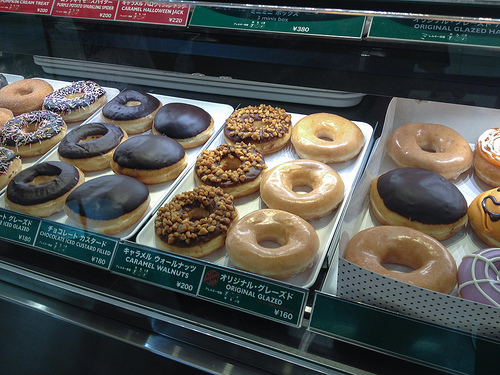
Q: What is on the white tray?
A: Doughnuts.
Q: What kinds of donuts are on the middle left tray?
A: Chocolate frosting donuts.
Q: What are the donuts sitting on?
A: White trays.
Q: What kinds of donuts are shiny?
A: Glazed donuts.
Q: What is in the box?
A: Donuts.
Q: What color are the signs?
A: Red and green.